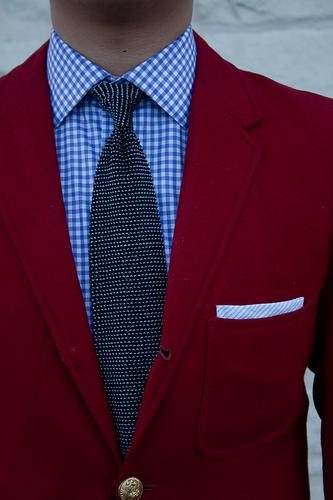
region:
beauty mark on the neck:
[120, 48, 129, 55]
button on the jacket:
[116, 476, 150, 498]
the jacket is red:
[2, 45, 324, 498]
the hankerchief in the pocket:
[210, 296, 308, 311]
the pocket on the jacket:
[202, 304, 316, 458]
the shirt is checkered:
[40, 23, 194, 313]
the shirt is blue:
[50, 34, 195, 323]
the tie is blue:
[91, 80, 178, 359]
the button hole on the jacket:
[153, 341, 176, 359]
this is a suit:
[199, 104, 324, 234]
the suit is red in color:
[246, 190, 319, 277]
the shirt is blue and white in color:
[144, 72, 184, 130]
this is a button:
[116, 477, 146, 497]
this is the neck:
[76, 10, 156, 52]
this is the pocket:
[203, 295, 309, 442]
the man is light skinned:
[109, 23, 147, 57]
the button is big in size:
[123, 477, 142, 498]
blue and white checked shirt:
[45, 30, 200, 321]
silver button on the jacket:
[119, 477, 145, 498]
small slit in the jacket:
[138, 482, 157, 491]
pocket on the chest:
[195, 294, 314, 457]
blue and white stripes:
[211, 296, 307, 321]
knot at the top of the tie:
[96, 77, 145, 131]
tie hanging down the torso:
[77, 80, 172, 497]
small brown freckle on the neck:
[122, 48, 129, 55]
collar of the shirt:
[40, 28, 210, 134]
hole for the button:
[159, 345, 170, 360]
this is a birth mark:
[121, 48, 128, 57]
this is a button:
[117, 477, 142, 499]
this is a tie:
[87, 82, 164, 454]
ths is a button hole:
[144, 481, 157, 492]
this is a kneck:
[54, 6, 182, 112]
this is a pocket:
[194, 308, 315, 457]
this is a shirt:
[52, 38, 178, 336]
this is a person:
[3, 0, 331, 499]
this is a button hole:
[158, 345, 175, 362]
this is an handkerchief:
[219, 294, 306, 317]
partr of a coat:
[282, 465, 285, 468]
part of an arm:
[289, 413, 304, 424]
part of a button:
[125, 455, 135, 489]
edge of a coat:
[195, 398, 208, 427]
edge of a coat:
[46, 404, 60, 417]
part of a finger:
[324, 416, 330, 420]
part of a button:
[126, 482, 132, 485]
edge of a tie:
[124, 383, 131, 395]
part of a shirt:
[209, 423, 216, 434]